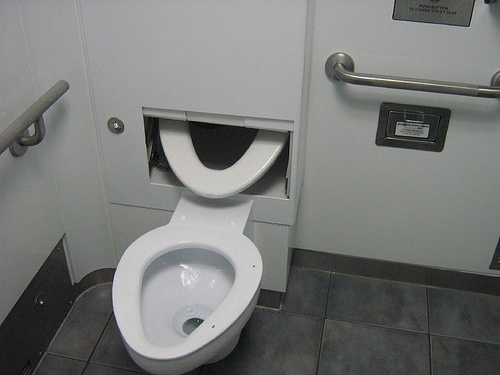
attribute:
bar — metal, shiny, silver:
[325, 52, 499, 104]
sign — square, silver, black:
[389, 0, 477, 27]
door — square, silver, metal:
[386, 109, 440, 145]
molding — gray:
[296, 245, 499, 295]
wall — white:
[300, 4, 499, 274]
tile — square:
[324, 266, 433, 339]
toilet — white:
[106, 195, 265, 371]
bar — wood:
[1, 77, 74, 157]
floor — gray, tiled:
[36, 260, 499, 374]